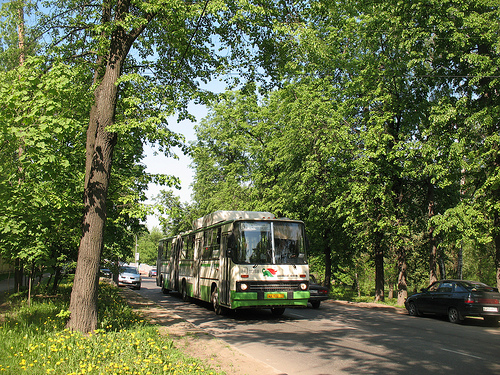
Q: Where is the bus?
A: Traveling down street.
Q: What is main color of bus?
A: White.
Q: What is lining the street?
A: Trees.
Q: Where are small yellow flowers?
A: In grass beside tree trunk.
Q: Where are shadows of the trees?
A: On the street.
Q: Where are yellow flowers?
A: Growing around tree.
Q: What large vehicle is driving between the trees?
A: A bus.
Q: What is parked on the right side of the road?
A: A car.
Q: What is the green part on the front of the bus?
A: The bumper.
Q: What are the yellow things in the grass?
A: Flowers.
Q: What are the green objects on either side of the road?
A: Trees.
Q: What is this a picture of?
A: Bus.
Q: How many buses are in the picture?
A: 1.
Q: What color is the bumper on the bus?
A: Green.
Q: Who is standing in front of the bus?
A: Nobody.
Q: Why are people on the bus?
A: Transportation.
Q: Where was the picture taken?
A: Road.